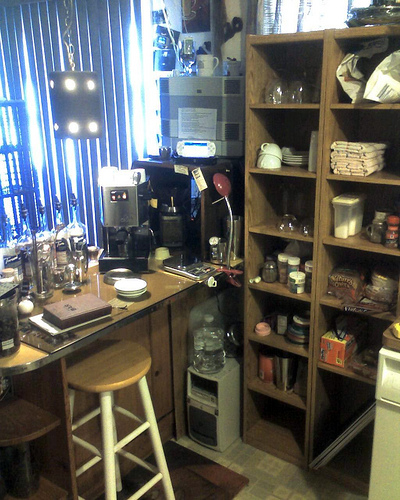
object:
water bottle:
[194, 314, 225, 374]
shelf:
[241, 19, 399, 497]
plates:
[114, 278, 149, 293]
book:
[43, 290, 113, 328]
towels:
[330, 139, 384, 153]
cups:
[254, 144, 284, 163]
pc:
[186, 360, 245, 453]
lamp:
[46, 64, 101, 142]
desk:
[1, 253, 243, 485]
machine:
[101, 167, 157, 272]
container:
[329, 191, 364, 239]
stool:
[54, 342, 174, 498]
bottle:
[68, 190, 91, 283]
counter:
[13, 245, 241, 353]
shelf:
[1, 403, 55, 464]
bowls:
[286, 311, 311, 345]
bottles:
[17, 200, 39, 295]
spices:
[259, 257, 281, 284]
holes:
[88, 121, 101, 135]